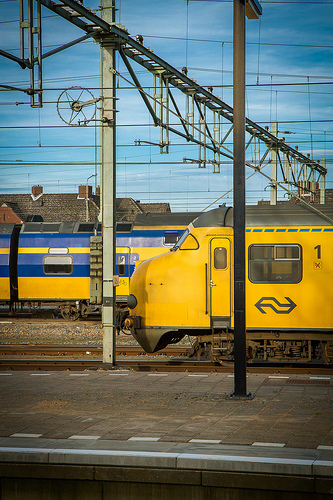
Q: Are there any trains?
A: Yes, there is a train.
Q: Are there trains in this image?
A: Yes, there is a train.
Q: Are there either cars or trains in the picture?
A: Yes, there is a train.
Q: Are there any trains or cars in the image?
A: Yes, there is a train.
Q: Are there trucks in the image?
A: No, there are no trucks.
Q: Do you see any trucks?
A: No, there are no trucks.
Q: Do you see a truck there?
A: No, there are no trucks.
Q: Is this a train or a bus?
A: This is a train.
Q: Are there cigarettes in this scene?
A: No, there are no cigarettes.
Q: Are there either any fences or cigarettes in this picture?
A: No, there are no cigarettes or fences.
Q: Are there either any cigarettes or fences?
A: No, there are no cigarettes or fences.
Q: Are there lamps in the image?
A: No, there are no lamps.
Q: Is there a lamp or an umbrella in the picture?
A: No, there are no lamps or umbrellas.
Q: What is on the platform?
A: The bricks are on the platform.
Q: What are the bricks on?
A: The bricks are on the platform.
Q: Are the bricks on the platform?
A: Yes, the bricks are on the platform.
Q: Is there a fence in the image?
A: No, there are no fences.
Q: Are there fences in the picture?
A: No, there are no fences.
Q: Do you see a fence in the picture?
A: No, there are no fences.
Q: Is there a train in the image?
A: Yes, there is a train.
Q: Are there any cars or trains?
A: Yes, there is a train.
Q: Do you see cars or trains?
A: Yes, there is a train.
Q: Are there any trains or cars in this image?
A: Yes, there is a train.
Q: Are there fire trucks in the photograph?
A: No, there are no fire trucks.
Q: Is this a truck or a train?
A: This is a train.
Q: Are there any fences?
A: No, there are no fences.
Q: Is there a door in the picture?
A: Yes, there is a door.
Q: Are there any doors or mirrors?
A: Yes, there is a door.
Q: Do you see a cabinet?
A: No, there are no cabinets.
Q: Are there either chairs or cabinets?
A: No, there are no cabinets or chairs.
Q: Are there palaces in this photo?
A: No, there are no palaces.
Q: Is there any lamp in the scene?
A: No, there are no lamps.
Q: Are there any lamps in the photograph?
A: No, there are no lamps.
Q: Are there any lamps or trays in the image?
A: No, there are no lamps or trays.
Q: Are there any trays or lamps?
A: No, there are no lamps or trays.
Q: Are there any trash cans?
A: No, there are no trash cans.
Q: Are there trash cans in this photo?
A: No, there are no trash cans.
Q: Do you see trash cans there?
A: No, there are no trash cans.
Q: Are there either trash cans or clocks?
A: No, there are no trash cans or clocks.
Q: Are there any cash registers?
A: No, there are no cash registers.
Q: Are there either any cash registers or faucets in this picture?
A: No, there are no cash registers or faucets.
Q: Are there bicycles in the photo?
A: No, there are no bicycles.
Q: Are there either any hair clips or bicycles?
A: No, there are no bicycles or hair clips.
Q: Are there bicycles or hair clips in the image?
A: No, there are no bicycles or hair clips.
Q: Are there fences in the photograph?
A: No, there are no fences.